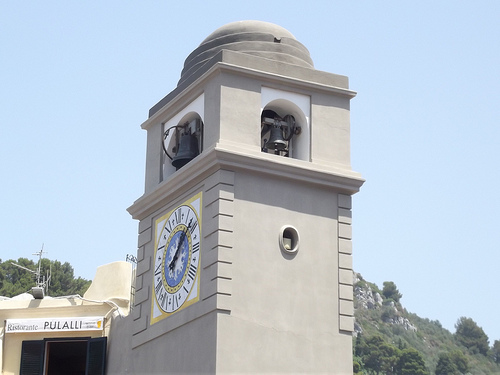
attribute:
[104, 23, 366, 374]
tower — grey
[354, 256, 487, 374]
hill — rocky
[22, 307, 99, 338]
sign — white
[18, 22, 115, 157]
sky — sunny, blue